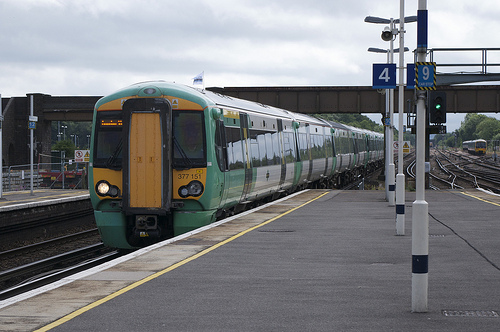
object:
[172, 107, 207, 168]
window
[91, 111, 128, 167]
window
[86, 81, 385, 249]
train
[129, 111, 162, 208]
door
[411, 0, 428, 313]
post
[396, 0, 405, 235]
post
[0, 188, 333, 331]
line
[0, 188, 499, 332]
pavement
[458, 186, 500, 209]
line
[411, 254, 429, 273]
blue section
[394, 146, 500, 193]
train tracks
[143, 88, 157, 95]
curved light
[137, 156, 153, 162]
handles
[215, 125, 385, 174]
side windows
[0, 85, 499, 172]
bridge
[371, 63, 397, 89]
blue sign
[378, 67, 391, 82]
white number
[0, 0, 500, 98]
skies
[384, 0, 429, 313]
white poles